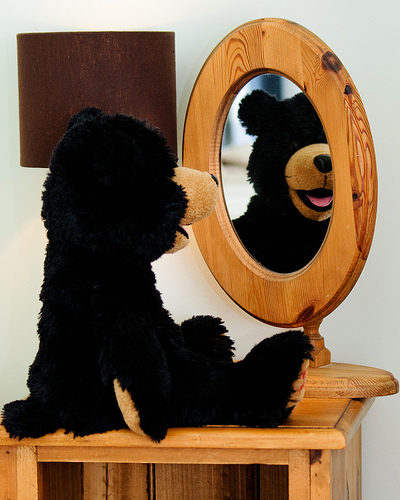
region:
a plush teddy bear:
[4, 100, 316, 449]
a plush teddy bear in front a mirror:
[0, 12, 385, 439]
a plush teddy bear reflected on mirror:
[217, 64, 348, 286]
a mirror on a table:
[177, 9, 396, 487]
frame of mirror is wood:
[176, 12, 388, 326]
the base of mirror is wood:
[251, 326, 398, 401]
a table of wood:
[2, 391, 381, 498]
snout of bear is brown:
[172, 160, 222, 249]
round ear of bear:
[234, 81, 284, 145]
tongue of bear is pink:
[280, 144, 334, 218]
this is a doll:
[39, 99, 174, 415]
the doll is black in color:
[72, 169, 124, 286]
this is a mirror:
[224, 92, 313, 233]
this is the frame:
[216, 43, 290, 65]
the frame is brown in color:
[255, 273, 328, 311]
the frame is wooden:
[272, 278, 326, 305]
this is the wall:
[349, 9, 399, 43]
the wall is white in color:
[357, 5, 398, 32]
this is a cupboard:
[246, 441, 336, 497]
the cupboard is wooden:
[244, 419, 314, 487]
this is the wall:
[350, 317, 388, 343]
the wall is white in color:
[362, 431, 388, 465]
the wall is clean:
[368, 416, 393, 466]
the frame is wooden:
[252, 33, 290, 59]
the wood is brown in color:
[306, 416, 331, 441]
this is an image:
[243, 87, 300, 193]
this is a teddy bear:
[27, 84, 313, 440]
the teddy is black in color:
[102, 275, 141, 311]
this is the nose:
[208, 179, 223, 184]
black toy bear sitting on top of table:
[0, 100, 328, 444]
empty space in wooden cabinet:
[0, 424, 336, 496]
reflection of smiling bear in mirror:
[180, 16, 376, 325]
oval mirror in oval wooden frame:
[180, 16, 376, 325]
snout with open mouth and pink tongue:
[284, 140, 332, 220]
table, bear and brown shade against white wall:
[0, 0, 396, 496]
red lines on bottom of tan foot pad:
[284, 356, 304, 420]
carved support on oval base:
[296, 320, 396, 396]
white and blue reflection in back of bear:
[216, 64, 300, 221]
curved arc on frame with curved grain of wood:
[341, 80, 381, 264]